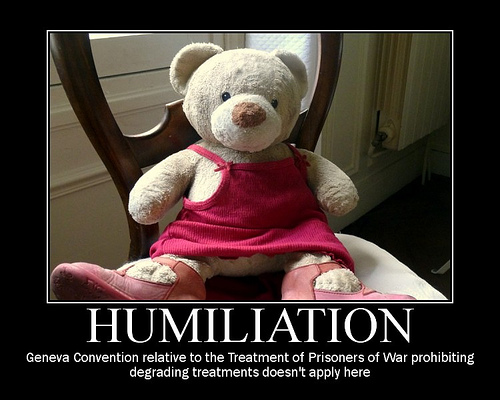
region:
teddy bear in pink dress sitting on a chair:
[47, 30, 450, 301]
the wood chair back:
[47, 29, 343, 256]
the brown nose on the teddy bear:
[231, 102, 267, 129]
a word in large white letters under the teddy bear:
[85, 304, 412, 343]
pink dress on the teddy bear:
[151, 143, 348, 255]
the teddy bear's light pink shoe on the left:
[48, 259, 204, 302]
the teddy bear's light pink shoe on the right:
[280, 260, 413, 302]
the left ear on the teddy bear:
[169, 42, 221, 94]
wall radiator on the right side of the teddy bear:
[370, 30, 452, 149]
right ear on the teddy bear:
[272, 52, 308, 99]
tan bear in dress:
[193, 50, 304, 261]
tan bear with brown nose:
[220, 92, 270, 137]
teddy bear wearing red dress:
[165, 100, 376, 270]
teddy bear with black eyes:
[210, 90, 231, 105]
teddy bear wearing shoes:
[293, 246, 420, 298]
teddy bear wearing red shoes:
[88, 253, 276, 280]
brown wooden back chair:
[103, 106, 212, 153]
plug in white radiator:
[371, 110, 427, 165]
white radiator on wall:
[373, 98, 435, 138]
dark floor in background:
[409, 212, 440, 262]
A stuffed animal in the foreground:
[48, 37, 424, 303]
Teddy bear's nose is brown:
[230, 101, 266, 131]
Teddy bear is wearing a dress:
[135, 134, 358, 271]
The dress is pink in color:
[143, 123, 360, 273]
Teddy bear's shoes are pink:
[45, 239, 427, 306]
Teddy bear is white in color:
[48, 28, 429, 300]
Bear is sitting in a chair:
[51, 34, 448, 303]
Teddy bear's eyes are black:
[218, 89, 283, 115]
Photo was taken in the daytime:
[48, 33, 454, 300]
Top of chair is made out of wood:
[51, 32, 361, 247]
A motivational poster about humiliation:
[3, 0, 498, 398]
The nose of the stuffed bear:
[231, 102, 263, 124]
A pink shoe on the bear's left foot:
[286, 263, 405, 303]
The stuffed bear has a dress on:
[165, 152, 351, 256]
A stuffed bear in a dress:
[71, 50, 413, 297]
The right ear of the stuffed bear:
[165, 45, 229, 82]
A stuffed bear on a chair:
[55, 35, 437, 299]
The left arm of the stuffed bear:
[305, 162, 364, 213]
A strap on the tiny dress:
[192, 145, 217, 162]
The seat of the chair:
[362, 254, 415, 287]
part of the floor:
[381, 209, 394, 231]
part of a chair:
[116, 123, 133, 155]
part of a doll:
[138, 188, 186, 215]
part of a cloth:
[243, 218, 266, 228]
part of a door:
[346, 114, 362, 149]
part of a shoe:
[111, 288, 117, 292]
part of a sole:
[71, 275, 82, 285]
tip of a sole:
[61, 264, 64, 274]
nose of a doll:
[241, 94, 268, 126]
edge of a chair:
[96, 151, 106, 164]